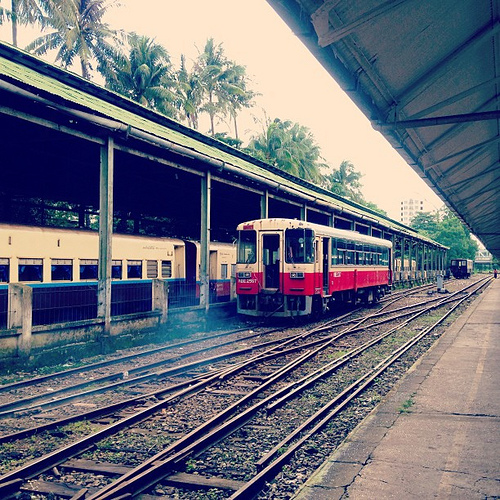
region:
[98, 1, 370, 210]
Palm trees behind the station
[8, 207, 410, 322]
Old trains on tracks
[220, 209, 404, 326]
Red and white pattern on train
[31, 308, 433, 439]
Criss-crossing tracks abound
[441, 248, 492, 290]
Solitary car in the distance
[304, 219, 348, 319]
Train door wide open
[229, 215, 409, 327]
Quite old passenger train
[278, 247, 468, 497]
Platform looks cracked and rundown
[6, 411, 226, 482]
Grass growing between tracks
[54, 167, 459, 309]
Steel support beams in a row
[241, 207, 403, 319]
red and white train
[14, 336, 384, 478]
older train tracks with grass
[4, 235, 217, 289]
white train with blue stripe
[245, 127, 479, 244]
trees and sky in background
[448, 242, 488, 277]
dark colored train in background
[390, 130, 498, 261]
roofing to the right side of tracks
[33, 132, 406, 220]
roofing to the left side of tracks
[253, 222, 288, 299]
front windows of red and white train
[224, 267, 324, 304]
headlights of red and white train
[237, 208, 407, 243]
roof of red and white train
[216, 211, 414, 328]
red and white train on tracks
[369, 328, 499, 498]
concrete train platform on side of tracks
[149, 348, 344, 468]
train tracks on the ground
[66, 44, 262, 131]
palm trees in the background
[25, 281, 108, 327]
black fence near the train tracks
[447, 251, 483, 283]
train on tracks in the back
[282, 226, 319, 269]
front window of a train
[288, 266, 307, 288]
front light of a train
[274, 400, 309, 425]
gravel and grass in between tracks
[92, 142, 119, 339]
metal support beams of a train station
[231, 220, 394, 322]
a red and white train car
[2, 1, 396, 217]
a row of palm trees in the background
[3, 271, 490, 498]
several train tracks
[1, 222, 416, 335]
a white train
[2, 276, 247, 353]
a concrete fence between the two trains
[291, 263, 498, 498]
a cracked concrete platform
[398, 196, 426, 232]
a tall white building in the background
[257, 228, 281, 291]
the front door of the red train car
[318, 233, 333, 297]
the side door of the red train car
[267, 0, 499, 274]
an awning hanging over the platform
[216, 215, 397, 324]
a red and white train on a track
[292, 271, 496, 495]
a paved platform next to a track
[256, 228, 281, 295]
a door on a train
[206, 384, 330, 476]
gravel along the tracks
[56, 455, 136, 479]
wood between the tracks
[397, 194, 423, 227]
a tall white building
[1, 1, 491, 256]
the visible sky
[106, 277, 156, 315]
railing alonside train tracks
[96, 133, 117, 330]
a tall metal support post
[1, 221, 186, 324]
a white train car